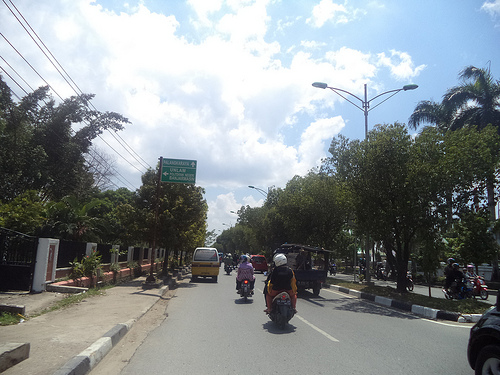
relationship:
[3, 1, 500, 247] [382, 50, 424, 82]
sky has cloud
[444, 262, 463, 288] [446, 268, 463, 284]
person wearing shirt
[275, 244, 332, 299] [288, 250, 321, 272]
truck carrying items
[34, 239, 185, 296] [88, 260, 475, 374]
retaining wall on side of road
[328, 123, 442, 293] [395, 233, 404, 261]
tree has stem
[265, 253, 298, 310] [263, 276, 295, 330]
man on motorcycle